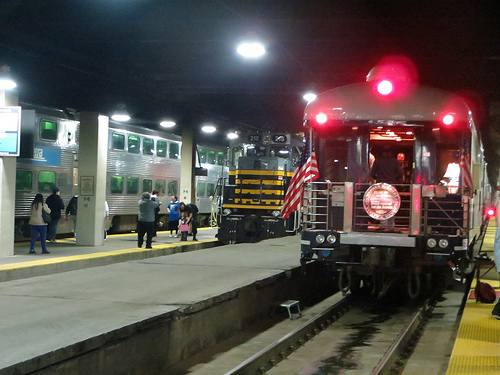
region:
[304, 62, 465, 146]
THE LIGHTS ARE RED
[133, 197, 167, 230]
THE MAN IS WEARING A GREY SHIRT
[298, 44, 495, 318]
THIS IS A TRAIN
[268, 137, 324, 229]
THE FLAG IS AMERICAN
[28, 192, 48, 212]
THE WOMAN HAS LONG HAIR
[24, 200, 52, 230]
THE WOMAN IS WEARING A JACKET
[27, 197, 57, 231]
THE WOMAN'S JACKET IS WHITE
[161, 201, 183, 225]
THE WOMAN IS WEARING A BLUE SHIRT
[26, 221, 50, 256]
THE WOMAN IS WEARING BLUE JEANS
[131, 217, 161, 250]
THE MAN IS WEARING BLACK PANTS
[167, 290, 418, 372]
A train track near the platform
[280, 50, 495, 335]
A train in the platform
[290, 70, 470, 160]
A red color lights in the trains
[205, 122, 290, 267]
A train near by the train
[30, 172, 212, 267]
Passengers walking in the railway station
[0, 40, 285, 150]
White colored lights in the railway station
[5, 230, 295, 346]
Railway platform near the train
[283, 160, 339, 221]
Flags flying in the train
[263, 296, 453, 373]
Metal railway track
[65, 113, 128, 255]
Pillar of the railway station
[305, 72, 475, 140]
three red lights on train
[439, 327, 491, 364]
yellow edge of platform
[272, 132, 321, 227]
american flag on train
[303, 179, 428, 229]
metal railing on train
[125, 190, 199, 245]
people on train platform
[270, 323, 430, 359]
metal rails of train track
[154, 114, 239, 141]
white lights on ceiling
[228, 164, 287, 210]
yellow and black stripes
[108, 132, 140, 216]
train with two levels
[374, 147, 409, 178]
people inside of train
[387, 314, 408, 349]
edge of a rail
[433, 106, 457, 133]
part of a light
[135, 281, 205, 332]
edge of a floor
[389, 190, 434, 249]
part of a balcony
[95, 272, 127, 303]
part of a floor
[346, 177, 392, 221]
part of a budge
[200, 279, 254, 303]
part of an edge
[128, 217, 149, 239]
part of a trouser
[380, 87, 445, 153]
part of a train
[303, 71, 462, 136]
Red brake lights on train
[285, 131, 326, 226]
American flag on back of train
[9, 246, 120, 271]
Yellow paint on edge of platform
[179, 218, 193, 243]
Child wearing a pink shirt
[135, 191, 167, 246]
Person taking a picture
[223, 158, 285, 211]
Yellow and black paint on front of train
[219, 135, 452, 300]
Two trains atopped at train station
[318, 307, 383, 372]
Water on cement on train tracks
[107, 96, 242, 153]
Lights above train platform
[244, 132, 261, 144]
Train identification number